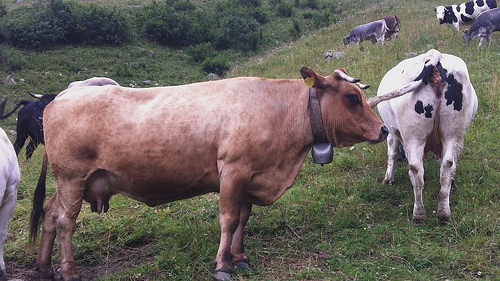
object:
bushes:
[264, 0, 342, 39]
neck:
[468, 22, 478, 38]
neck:
[345, 31, 355, 41]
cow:
[363, 48, 476, 224]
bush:
[0, 0, 137, 50]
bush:
[132, 0, 209, 44]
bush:
[205, 0, 271, 50]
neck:
[288, 76, 337, 153]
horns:
[356, 81, 368, 88]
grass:
[0, 0, 500, 281]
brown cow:
[30, 62, 388, 281]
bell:
[310, 142, 335, 166]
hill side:
[249, 22, 254, 29]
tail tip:
[25, 145, 52, 246]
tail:
[365, 48, 442, 108]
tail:
[0, 98, 31, 121]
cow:
[0, 90, 52, 160]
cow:
[462, 7, 500, 44]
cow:
[433, 0, 497, 36]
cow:
[372, 15, 402, 41]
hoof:
[412, 214, 425, 225]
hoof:
[434, 208, 451, 224]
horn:
[334, 68, 361, 83]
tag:
[303, 76, 315, 87]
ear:
[300, 64, 327, 90]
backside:
[377, 48, 478, 227]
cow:
[339, 20, 388, 53]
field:
[0, 0, 500, 281]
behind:
[400, 51, 474, 227]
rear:
[365, 49, 476, 225]